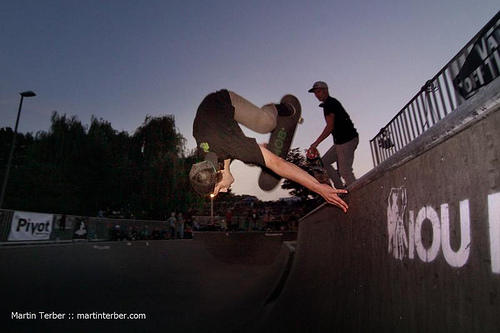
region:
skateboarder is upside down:
[188, 83, 351, 213]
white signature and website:
[7, 308, 147, 323]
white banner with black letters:
[6, 205, 56, 247]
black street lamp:
[13, 85, 40, 133]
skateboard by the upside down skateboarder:
[256, 92, 308, 192]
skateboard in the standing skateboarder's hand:
[303, 144, 334, 203]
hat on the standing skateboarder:
[305, 80, 332, 93]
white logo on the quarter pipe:
[378, 178, 498, 275]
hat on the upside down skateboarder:
[185, 149, 221, 200]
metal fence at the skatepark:
[367, 15, 498, 170]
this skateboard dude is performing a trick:
[180, 81, 355, 217]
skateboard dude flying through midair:
[178, 80, 355, 218]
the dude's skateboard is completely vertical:
[251, 85, 307, 196]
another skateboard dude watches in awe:
[296, 72, 366, 201]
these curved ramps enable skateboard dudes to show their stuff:
[1, 198, 325, 330]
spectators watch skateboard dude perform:
[68, 196, 320, 238]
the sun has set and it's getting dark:
[3, 5, 495, 182]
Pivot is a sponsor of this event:
[3, 206, 59, 246]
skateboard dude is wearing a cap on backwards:
[184, 146, 224, 206]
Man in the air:
[174, 75, 350, 225]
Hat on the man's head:
[176, 149, 224, 199]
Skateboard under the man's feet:
[245, 86, 311, 195]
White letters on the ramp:
[372, 191, 498, 289]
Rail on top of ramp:
[359, 12, 498, 170]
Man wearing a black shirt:
[296, 76, 365, 193]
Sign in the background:
[7, 203, 57, 245]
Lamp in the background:
[2, 82, 39, 212]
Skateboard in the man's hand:
[297, 143, 339, 193]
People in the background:
[89, 210, 204, 247]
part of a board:
[440, 130, 456, 170]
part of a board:
[313, 140, 324, 164]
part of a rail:
[172, 227, 177, 230]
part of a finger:
[225, 260, 235, 277]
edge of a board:
[282, 113, 284, 128]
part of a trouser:
[349, 150, 350, 165]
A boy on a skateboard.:
[187, 88, 349, 213]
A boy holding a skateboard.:
[303, 80, 360, 192]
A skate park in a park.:
[0, 12, 498, 331]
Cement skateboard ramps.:
[3, 78, 498, 331]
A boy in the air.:
[188, 86, 352, 216]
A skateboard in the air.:
[257, 93, 306, 193]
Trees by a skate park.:
[2, 109, 214, 221]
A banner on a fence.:
[6, 212, 55, 242]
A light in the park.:
[2, 89, 36, 205]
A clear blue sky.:
[0, 3, 499, 198]